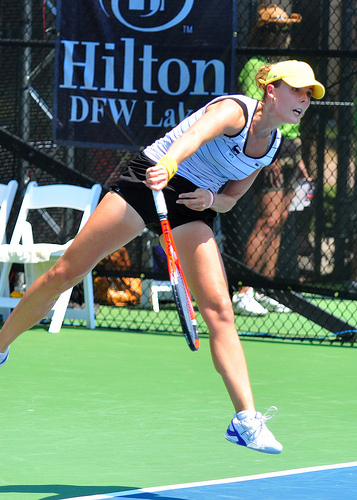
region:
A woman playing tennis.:
[18, 57, 347, 459]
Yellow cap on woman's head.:
[249, 52, 327, 111]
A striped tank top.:
[140, 83, 279, 197]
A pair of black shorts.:
[118, 143, 217, 231]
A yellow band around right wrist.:
[150, 151, 184, 192]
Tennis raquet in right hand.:
[145, 163, 209, 363]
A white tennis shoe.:
[226, 397, 283, 459]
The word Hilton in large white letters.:
[59, 30, 226, 96]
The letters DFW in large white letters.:
[64, 92, 141, 132]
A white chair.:
[11, 172, 103, 335]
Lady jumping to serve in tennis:
[0, 56, 319, 453]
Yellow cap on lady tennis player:
[257, 58, 322, 93]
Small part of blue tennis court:
[103, 462, 353, 497]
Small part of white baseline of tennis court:
[62, 460, 353, 496]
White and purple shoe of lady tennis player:
[222, 404, 283, 453]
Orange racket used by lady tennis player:
[151, 183, 198, 353]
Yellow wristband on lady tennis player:
[160, 158, 176, 177]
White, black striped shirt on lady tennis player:
[142, 91, 279, 189]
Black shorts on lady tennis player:
[112, 153, 211, 231]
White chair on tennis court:
[1, 181, 99, 332]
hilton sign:
[51, 5, 263, 181]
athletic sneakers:
[214, 390, 319, 469]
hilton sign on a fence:
[51, 0, 352, 144]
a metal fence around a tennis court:
[11, 2, 334, 472]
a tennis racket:
[97, 162, 233, 352]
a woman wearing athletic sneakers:
[140, 40, 305, 466]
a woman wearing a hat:
[221, 47, 355, 153]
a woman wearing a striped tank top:
[160, 15, 330, 224]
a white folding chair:
[7, 170, 123, 339]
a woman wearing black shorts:
[92, 40, 333, 284]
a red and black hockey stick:
[157, 219, 203, 352]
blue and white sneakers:
[223, 416, 281, 452]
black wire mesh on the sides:
[241, 196, 352, 344]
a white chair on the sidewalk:
[26, 179, 85, 218]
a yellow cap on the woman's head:
[268, 59, 321, 80]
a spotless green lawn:
[54, 331, 197, 418]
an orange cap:
[248, 1, 300, 30]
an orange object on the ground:
[96, 276, 138, 303]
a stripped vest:
[178, 102, 242, 178]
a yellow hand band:
[162, 155, 177, 176]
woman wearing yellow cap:
[265, 59, 325, 102]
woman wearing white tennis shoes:
[223, 409, 283, 452]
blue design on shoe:
[226, 418, 245, 445]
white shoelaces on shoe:
[243, 405, 276, 443]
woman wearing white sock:
[237, 410, 256, 420]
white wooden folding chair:
[2, 181, 101, 329]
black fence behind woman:
[0, 0, 355, 344]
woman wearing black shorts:
[110, 149, 222, 234]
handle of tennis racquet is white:
[146, 169, 169, 216]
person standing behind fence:
[232, 5, 310, 315]